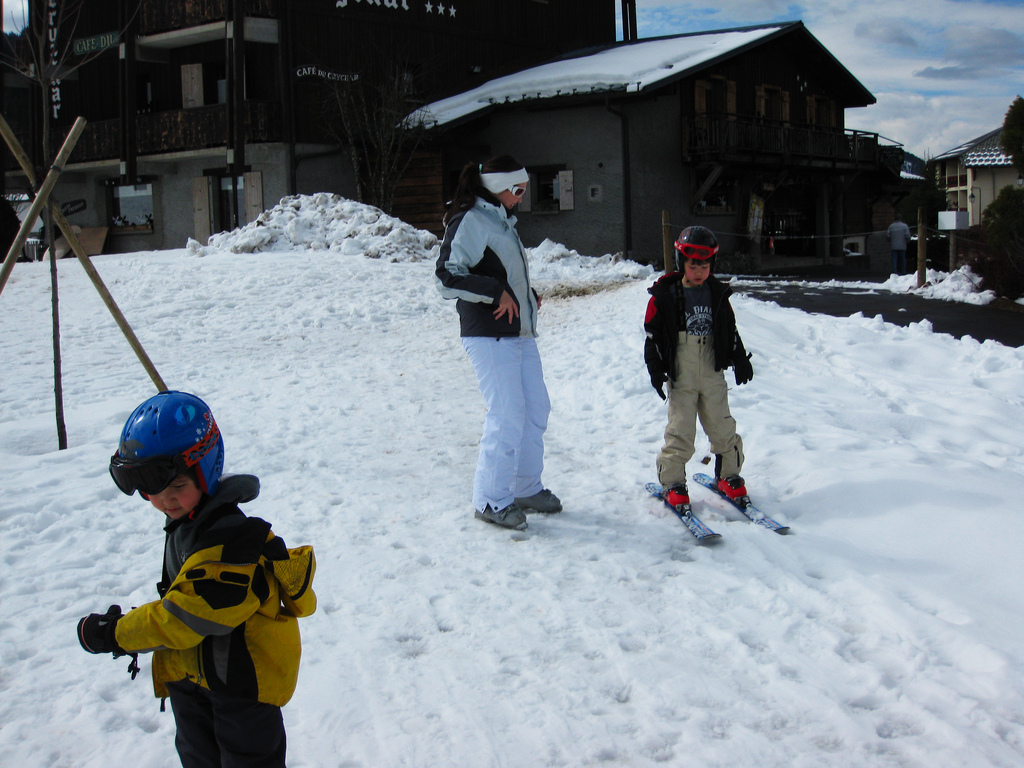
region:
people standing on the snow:
[27, 48, 1021, 763]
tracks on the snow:
[28, 169, 1015, 757]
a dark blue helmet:
[93, 330, 246, 521]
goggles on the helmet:
[81, 370, 240, 514]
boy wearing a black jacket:
[621, 226, 774, 407]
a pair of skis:
[627, 428, 812, 572]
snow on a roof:
[401, 11, 795, 189]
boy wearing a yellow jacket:
[31, 478, 348, 712]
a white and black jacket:
[394, 188, 584, 351]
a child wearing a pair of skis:
[639, 225, 792, 558]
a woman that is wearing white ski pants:
[441, 162, 560, 518]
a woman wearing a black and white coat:
[441, 152, 552, 339]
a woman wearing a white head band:
[446, 152, 533, 225]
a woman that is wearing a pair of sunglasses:
[472, 162, 534, 214]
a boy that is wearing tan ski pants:
[627, 228, 754, 488]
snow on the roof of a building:
[447, 21, 777, 136]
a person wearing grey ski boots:
[471, 480, 567, 539]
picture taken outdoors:
[21, 63, 1018, 749]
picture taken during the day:
[24, 11, 1020, 717]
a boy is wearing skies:
[630, 219, 776, 551]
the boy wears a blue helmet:
[125, 384, 212, 495]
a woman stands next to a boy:
[416, 141, 571, 528]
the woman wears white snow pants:
[456, 339, 559, 502]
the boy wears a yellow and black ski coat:
[83, 520, 343, 702]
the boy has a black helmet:
[674, 226, 709, 253]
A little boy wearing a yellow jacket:
[75, 388, 344, 724]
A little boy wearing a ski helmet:
[100, 383, 249, 524]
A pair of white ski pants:
[458, 310, 572, 535]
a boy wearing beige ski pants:
[637, 216, 778, 523]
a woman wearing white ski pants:
[441, 145, 584, 539]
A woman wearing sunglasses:
[467, 145, 541, 225]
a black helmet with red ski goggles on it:
[666, 219, 727, 283]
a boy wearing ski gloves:
[72, 382, 320, 709]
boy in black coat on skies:
[627, 217, 818, 550]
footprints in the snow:
[753, 574, 960, 720]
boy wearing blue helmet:
[67, 388, 318, 763]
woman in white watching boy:
[431, 150, 799, 561]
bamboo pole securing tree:
[0, 10, 193, 448]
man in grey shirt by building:
[874, 210, 916, 272]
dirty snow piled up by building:
[175, 182, 441, 280]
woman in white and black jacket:
[434, 150, 567, 534]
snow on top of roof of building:
[409, 14, 803, 231]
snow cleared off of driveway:
[741, 261, 999, 329]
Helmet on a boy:
[673, 221, 722, 289]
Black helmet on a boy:
[669, 222, 724, 292]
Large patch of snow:
[480, 594, 776, 735]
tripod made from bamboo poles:
[0, 114, 169, 454]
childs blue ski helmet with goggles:
[110, 391, 227, 497]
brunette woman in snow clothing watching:
[433, 151, 560, 529]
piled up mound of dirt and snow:
[183, 189, 459, 263]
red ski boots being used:
[659, 470, 754, 513]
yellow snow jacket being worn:
[110, 522, 322, 709]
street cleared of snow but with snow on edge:
[688, 263, 1022, 353]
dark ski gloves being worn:
[645, 348, 754, 402]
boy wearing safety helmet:
[112, 371, 237, 502]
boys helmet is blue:
[107, 378, 241, 506]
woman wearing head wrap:
[472, 156, 530, 195]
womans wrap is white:
[481, 159, 539, 195]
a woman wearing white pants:
[432, 145, 565, 537]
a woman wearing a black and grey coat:
[431, 151, 569, 531]